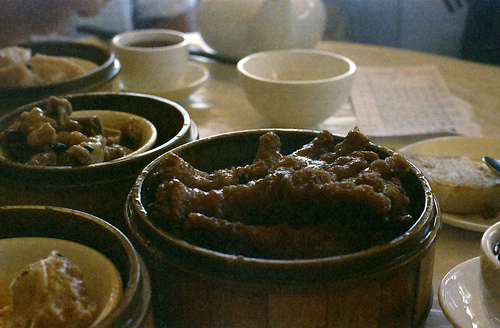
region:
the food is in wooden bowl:
[125, 117, 400, 251]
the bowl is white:
[230, 23, 370, 131]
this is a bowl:
[234, 39, 363, 114]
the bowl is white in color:
[298, 72, 347, 100]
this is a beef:
[245, 159, 342, 223]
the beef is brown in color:
[261, 175, 324, 222]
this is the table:
[408, 48, 498, 90]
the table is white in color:
[466, 65, 491, 112]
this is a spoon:
[476, 149, 499, 176]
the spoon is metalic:
[473, 150, 498, 172]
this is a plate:
[456, 208, 472, 232]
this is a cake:
[437, 148, 485, 191]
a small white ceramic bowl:
[239, 47, 359, 125]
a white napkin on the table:
[360, 65, 462, 137]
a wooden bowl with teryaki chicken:
[148, 129, 414, 325]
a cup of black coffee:
[112, 27, 197, 86]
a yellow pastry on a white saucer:
[425, 151, 489, 208]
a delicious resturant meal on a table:
[3, 22, 485, 327]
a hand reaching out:
[9, 2, 105, 25]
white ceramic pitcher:
[206, 5, 328, 51]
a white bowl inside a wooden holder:
[5, 236, 67, 258]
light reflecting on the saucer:
[454, 288, 474, 312]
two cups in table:
[93, 23, 400, 134]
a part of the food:
[21, 213, 157, 317]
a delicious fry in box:
[143, 114, 475, 296]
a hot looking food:
[138, 123, 485, 312]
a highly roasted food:
[129, 108, 491, 313]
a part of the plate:
[439, 253, 482, 324]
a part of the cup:
[466, 222, 498, 260]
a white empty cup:
[243, 31, 383, 128]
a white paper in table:
[338, 50, 453, 147]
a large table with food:
[16, 32, 496, 312]